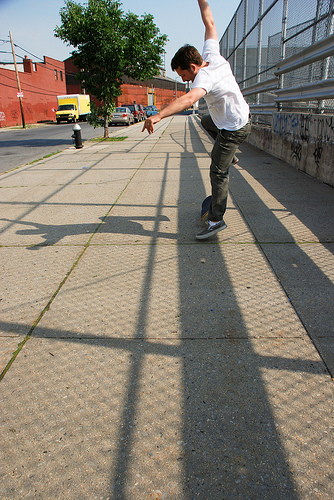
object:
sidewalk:
[9, 102, 330, 477]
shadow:
[0, 214, 180, 250]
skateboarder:
[201, 195, 213, 224]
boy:
[142, 0, 255, 242]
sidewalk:
[87, 134, 329, 312]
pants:
[207, 111, 253, 222]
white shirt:
[189, 38, 249, 132]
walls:
[17, 55, 57, 122]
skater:
[140, 0, 252, 241]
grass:
[88, 135, 132, 143]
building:
[116, 70, 166, 105]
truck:
[52, 90, 97, 122]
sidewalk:
[1, 245, 331, 499]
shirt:
[190, 41, 250, 131]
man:
[142, 0, 259, 242]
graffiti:
[275, 106, 334, 162]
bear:
[103, 98, 157, 128]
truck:
[56, 93, 92, 124]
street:
[5, 117, 61, 153]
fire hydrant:
[69, 121, 85, 149]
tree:
[53, 1, 170, 139]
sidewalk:
[7, 120, 167, 292]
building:
[0, 55, 54, 127]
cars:
[110, 107, 135, 127]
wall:
[252, 126, 274, 153]